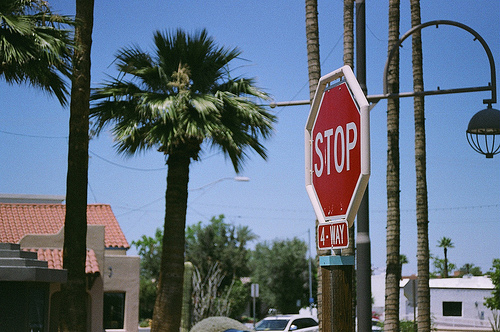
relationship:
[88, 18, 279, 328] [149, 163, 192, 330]
palm tree growing on trunk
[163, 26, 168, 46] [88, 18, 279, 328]
leaf growing on palm tree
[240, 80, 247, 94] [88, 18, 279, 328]
leaf growing on palm tree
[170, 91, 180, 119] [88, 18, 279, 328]
leaf growing on palm tree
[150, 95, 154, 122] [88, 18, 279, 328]
leaf growing on palm tree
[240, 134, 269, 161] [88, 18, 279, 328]
leaf growing on palm tree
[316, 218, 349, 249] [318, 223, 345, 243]
sign says 4-way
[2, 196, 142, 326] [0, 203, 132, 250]
building with tile roof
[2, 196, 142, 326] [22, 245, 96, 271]
building with roof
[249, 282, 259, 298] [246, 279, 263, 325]
sign on pole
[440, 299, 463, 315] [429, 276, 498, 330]
window in building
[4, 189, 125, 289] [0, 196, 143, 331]
tile above building